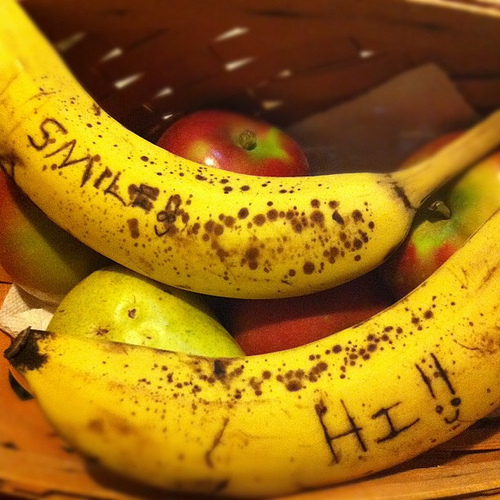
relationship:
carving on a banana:
[294, 354, 466, 469] [0, 204, 499, 499]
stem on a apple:
[221, 127, 270, 154] [157, 109, 314, 181]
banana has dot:
[4, 211, 499, 498] [130, 271, 441, 421]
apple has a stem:
[136, 96, 314, 181] [236, 128, 258, 151]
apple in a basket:
[223, 293, 412, 361] [0, 0, 500, 500]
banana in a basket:
[0, 0, 500, 301] [0, 0, 500, 500]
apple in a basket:
[157, 109, 314, 181] [0, 0, 500, 500]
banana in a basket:
[0, 204, 499, 499] [0, 0, 500, 500]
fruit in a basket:
[45, 264, 241, 358] [0, 0, 500, 500]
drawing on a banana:
[26, 117, 181, 237] [0, 0, 500, 301]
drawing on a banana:
[26, 117, 181, 237] [4, 211, 499, 498]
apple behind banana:
[157, 109, 314, 181] [0, 0, 500, 301]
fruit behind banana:
[45, 264, 246, 358] [2, 295, 494, 466]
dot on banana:
[165, 171, 379, 289] [0, 0, 500, 301]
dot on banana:
[130, 271, 441, 421] [4, 211, 499, 498]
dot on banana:
[165, 171, 379, 289] [308, 194, 387, 246]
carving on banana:
[313, 350, 465, 468] [6, 307, 496, 483]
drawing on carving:
[26, 117, 181, 237] [313, 350, 465, 468]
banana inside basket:
[0, 204, 499, 499] [4, 2, 498, 496]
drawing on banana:
[26, 117, 181, 237] [156, 167, 361, 284]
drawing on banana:
[26, 117, 181, 237] [0, 0, 500, 301]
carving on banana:
[313, 350, 465, 468] [49, 279, 498, 486]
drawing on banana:
[148, 183, 189, 253] [2, 68, 499, 321]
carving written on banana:
[313, 350, 465, 468] [0, 204, 499, 499]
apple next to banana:
[157, 109, 314, 181] [0, 0, 500, 301]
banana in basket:
[0, 0, 500, 301] [4, 2, 498, 496]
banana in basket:
[0, 204, 499, 499] [4, 2, 498, 496]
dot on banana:
[165, 171, 379, 289] [0, 204, 499, 499]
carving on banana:
[313, 350, 465, 468] [55, 57, 480, 484]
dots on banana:
[149, 414, 205, 481] [4, 211, 499, 498]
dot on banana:
[165, 171, 379, 289] [1, 59, 496, 297]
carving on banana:
[313, 350, 465, 468] [1, 295, 499, 490]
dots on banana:
[87, 414, 121, 442] [4, 211, 499, 498]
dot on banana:
[130, 410, 137, 418] [4, 211, 499, 498]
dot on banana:
[348, 210, 361, 223] [0, 0, 500, 301]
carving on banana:
[313, 350, 465, 468] [4, 211, 499, 498]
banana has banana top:
[0, 0, 500, 301] [2, 312, 60, 387]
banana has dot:
[0, 2, 496, 254] [165, 171, 379, 289]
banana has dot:
[0, 204, 499, 499] [130, 271, 441, 421]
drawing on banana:
[26, 117, 181, 237] [44, 111, 429, 498]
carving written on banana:
[313, 350, 465, 468] [4, 211, 499, 498]